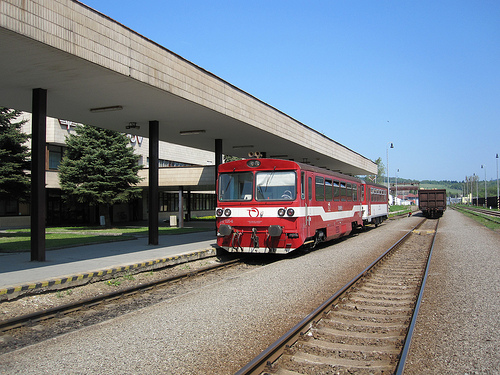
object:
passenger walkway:
[0, 229, 216, 288]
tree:
[55, 124, 145, 226]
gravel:
[278, 354, 397, 375]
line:
[212, 203, 306, 222]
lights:
[87, 105, 124, 113]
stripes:
[0, 286, 8, 296]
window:
[216, 171, 252, 202]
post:
[147, 121, 159, 246]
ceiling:
[0, 26, 378, 176]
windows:
[308, 176, 313, 201]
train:
[214, 158, 388, 255]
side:
[301, 169, 389, 244]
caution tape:
[0, 249, 217, 296]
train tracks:
[226, 212, 439, 375]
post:
[31, 85, 46, 265]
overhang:
[0, 1, 381, 176]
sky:
[74, 0, 500, 181]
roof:
[388, 186, 419, 191]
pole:
[387, 141, 390, 214]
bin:
[169, 212, 179, 227]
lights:
[216, 209, 224, 216]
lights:
[493, 152, 500, 160]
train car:
[418, 189, 447, 219]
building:
[0, 109, 226, 230]